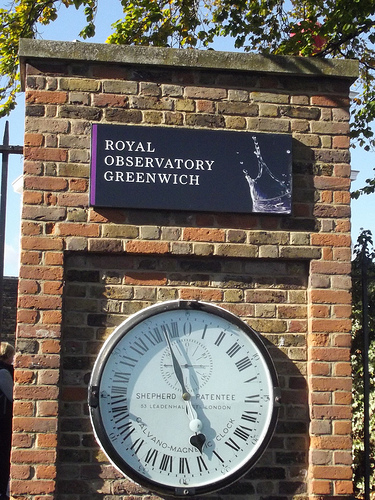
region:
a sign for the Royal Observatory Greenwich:
[88, 121, 295, 214]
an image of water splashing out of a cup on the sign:
[234, 131, 293, 214]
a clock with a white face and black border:
[84, 294, 281, 498]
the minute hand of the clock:
[159, 323, 192, 396]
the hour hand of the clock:
[183, 392, 208, 455]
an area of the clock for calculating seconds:
[157, 338, 216, 394]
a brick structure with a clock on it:
[6, 34, 355, 499]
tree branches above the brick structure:
[1, 0, 374, 83]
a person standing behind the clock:
[0, 338, 18, 498]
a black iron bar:
[355, 253, 373, 499]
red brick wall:
[31, 78, 346, 126]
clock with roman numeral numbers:
[89, 301, 276, 491]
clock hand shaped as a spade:
[184, 434, 220, 455]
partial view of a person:
[0, 328, 13, 433]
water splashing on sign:
[239, 134, 292, 214]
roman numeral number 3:
[225, 338, 243, 357]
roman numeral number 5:
[240, 371, 269, 391]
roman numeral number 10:
[208, 443, 229, 468]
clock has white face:
[106, 306, 276, 489]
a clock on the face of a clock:
[153, 333, 213, 394]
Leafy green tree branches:
[1, 0, 373, 199]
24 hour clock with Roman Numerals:
[83, 295, 279, 499]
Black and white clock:
[86, 293, 276, 499]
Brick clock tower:
[8, 100, 353, 498]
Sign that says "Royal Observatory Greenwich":
[84, 117, 303, 220]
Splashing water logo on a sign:
[227, 133, 294, 212]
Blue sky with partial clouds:
[1, 0, 372, 275]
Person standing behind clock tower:
[1, 339, 15, 498]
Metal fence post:
[347, 226, 372, 497]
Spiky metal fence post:
[0, 113, 25, 355]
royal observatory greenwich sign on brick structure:
[90, 124, 294, 220]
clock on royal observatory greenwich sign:
[90, 298, 280, 498]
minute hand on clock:
[160, 323, 185, 392]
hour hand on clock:
[185, 399, 206, 458]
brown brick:
[278, 245, 322, 258]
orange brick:
[311, 232, 351, 247]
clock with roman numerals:
[198, 322, 210, 338]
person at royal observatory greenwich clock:
[0, 337, 17, 499]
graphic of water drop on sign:
[230, 133, 291, 215]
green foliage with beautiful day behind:
[108, 1, 155, 46]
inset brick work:
[57, 240, 127, 312]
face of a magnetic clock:
[84, 292, 282, 494]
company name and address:
[131, 385, 236, 410]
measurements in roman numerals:
[212, 319, 260, 372]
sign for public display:
[87, 115, 291, 216]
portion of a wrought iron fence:
[0, 105, 18, 270]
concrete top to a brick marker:
[22, 30, 353, 87]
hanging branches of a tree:
[122, 0, 287, 41]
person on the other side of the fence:
[0, 311, 10, 402]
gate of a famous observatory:
[7, 15, 355, 480]